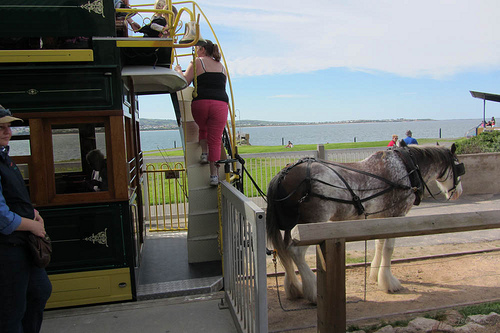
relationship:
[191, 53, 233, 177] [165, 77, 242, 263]
woman on stairs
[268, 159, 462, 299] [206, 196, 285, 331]
horse behind fence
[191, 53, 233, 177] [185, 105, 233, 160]
woman has pants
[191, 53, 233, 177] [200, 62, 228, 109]
woman has shirt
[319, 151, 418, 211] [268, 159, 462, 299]
straps on horse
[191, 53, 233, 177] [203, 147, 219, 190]
woman wears shoes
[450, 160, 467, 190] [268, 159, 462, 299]
blinders on horse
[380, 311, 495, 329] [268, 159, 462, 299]
stones near horse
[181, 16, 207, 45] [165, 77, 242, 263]
bell atop stairs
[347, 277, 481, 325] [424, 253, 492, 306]
shadoow on dirt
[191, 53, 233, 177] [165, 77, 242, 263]
woman climbs stairs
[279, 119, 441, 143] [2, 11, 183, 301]
water behind building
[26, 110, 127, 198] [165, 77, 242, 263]
window below stairs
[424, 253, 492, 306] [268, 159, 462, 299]
dirt under horse